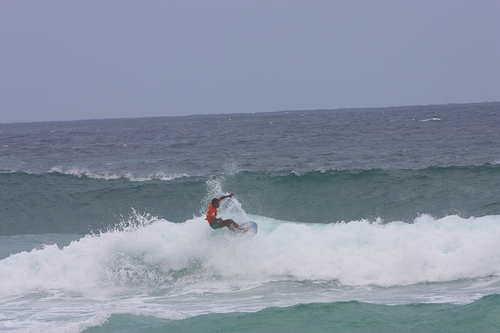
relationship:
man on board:
[205, 193, 248, 234] [234, 219, 256, 239]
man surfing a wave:
[205, 193, 248, 234] [5, 200, 484, 308]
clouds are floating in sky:
[390, 38, 460, 92] [347, 16, 487, 97]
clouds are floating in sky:
[0, 0, 500, 123] [21, 13, 411, 73]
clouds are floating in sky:
[0, 0, 500, 123] [37, 16, 496, 80]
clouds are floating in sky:
[0, 0, 500, 123] [77, 23, 495, 77]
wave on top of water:
[0, 192, 500, 333] [9, 198, 182, 319]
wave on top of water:
[0, 192, 500, 333] [23, 160, 463, 327]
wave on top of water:
[146, 230, 205, 272] [38, 165, 487, 319]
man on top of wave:
[194, 193, 243, 233] [139, 201, 406, 260]